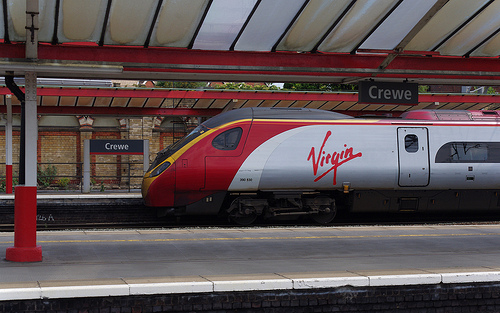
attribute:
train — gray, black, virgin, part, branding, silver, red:
[140, 105, 497, 223]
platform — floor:
[0, 187, 499, 312]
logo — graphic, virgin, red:
[306, 127, 365, 187]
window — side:
[435, 140, 499, 163]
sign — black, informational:
[90, 139, 140, 154]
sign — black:
[360, 80, 420, 106]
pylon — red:
[5, 186, 45, 265]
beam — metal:
[4, 96, 14, 163]